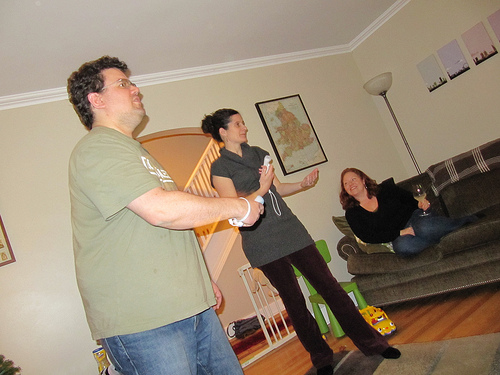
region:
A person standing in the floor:
[31, 15, 191, 300]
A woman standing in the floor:
[236, 110, 399, 352]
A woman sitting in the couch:
[331, 152, 483, 263]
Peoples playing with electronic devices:
[243, 148, 302, 229]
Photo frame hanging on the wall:
[254, 95, 346, 165]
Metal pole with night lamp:
[360, 63, 421, 155]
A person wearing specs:
[109, 72, 139, 98]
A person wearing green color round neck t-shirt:
[60, 145, 195, 316]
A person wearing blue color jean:
[126, 320, 261, 362]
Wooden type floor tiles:
[428, 304, 498, 327]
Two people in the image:
[42, 49, 487, 372]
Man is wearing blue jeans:
[90, 304, 259, 374]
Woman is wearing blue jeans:
[388, 204, 491, 264]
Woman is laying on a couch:
[328, 142, 499, 319]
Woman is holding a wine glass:
[400, 173, 436, 227]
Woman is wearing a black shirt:
[335, 179, 429, 249]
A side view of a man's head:
[54, 46, 151, 149]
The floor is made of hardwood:
[212, 287, 495, 374]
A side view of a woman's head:
[197, 97, 261, 163]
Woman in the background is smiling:
[329, 163, 379, 210]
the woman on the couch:
[319, 150, 458, 261]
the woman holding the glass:
[403, 180, 435, 222]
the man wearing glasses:
[59, 60, 159, 130]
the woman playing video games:
[185, 107, 397, 348]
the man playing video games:
[30, 62, 286, 369]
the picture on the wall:
[251, 86, 331, 166]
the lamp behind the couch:
[353, 73, 423, 170]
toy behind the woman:
[345, 296, 409, 338]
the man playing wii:
[36, 55, 280, 373]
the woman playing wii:
[180, 103, 406, 369]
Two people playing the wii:
[59, 55, 421, 374]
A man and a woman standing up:
[58, 60, 409, 374]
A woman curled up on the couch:
[323, 160, 471, 267]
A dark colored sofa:
[332, 143, 499, 305]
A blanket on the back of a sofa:
[415, 137, 497, 206]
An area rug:
[316, 329, 498, 372]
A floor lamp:
[356, 70, 433, 180]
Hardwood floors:
[200, 266, 494, 373]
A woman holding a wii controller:
[195, 103, 417, 370]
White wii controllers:
[224, 149, 283, 234]